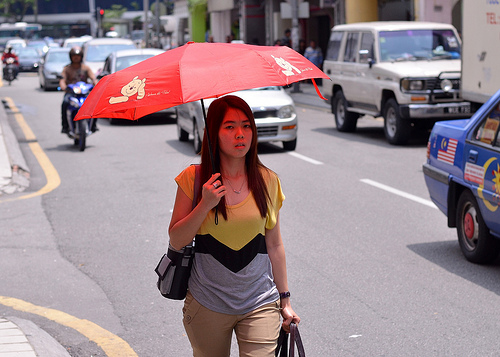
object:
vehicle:
[173, 80, 301, 155]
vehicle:
[77, 37, 136, 76]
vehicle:
[36, 44, 75, 92]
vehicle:
[5, 36, 43, 70]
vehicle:
[62, 35, 96, 51]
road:
[114, 122, 423, 341]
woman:
[165, 88, 300, 356]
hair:
[200, 95, 274, 221]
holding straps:
[277, 317, 305, 357]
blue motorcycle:
[56, 80, 100, 152]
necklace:
[222, 174, 250, 195]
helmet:
[69, 47, 85, 64]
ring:
[212, 182, 218, 188]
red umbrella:
[70, 39, 329, 186]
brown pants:
[180, 294, 284, 357]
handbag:
[277, 318, 308, 357]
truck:
[319, 20, 469, 146]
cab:
[420, 81, 500, 275]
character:
[108, 75, 148, 105]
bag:
[153, 244, 195, 301]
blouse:
[172, 162, 287, 315]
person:
[59, 46, 101, 133]